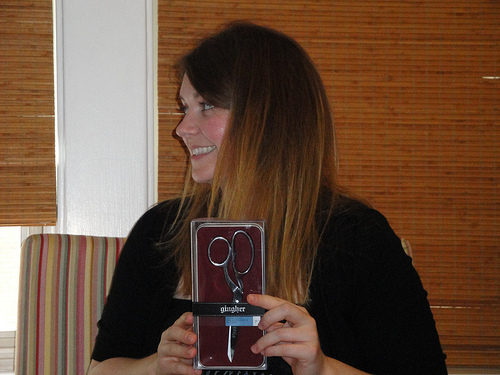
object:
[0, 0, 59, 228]
window shade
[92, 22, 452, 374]
woman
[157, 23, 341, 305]
hair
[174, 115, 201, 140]
nose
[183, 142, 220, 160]
mouth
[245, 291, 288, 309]
finger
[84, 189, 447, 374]
shirt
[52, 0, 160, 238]
wall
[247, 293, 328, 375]
hand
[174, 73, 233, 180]
face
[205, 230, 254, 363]
scissors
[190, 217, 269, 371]
box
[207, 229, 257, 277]
handle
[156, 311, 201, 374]
hand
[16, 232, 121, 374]
seat cushion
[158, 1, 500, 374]
shade